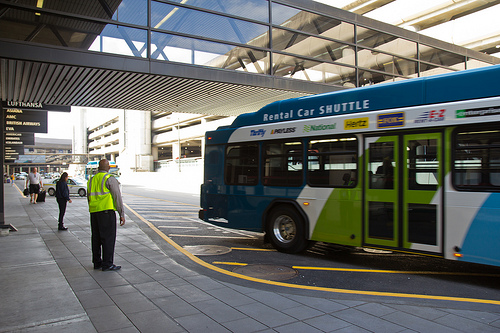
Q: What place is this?
A: It is a garage.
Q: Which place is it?
A: It is a garage.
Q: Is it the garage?
A: Yes, it is the garage.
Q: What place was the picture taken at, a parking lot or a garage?
A: It was taken at a garage.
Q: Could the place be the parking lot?
A: No, it is the garage.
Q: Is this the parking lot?
A: No, it is the garage.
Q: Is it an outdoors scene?
A: Yes, it is outdoors.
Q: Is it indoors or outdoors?
A: It is outdoors.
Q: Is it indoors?
A: No, it is outdoors.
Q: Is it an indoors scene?
A: No, it is outdoors.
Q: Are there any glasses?
A: No, there are no glasses.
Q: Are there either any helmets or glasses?
A: No, there are no glasses or helmets.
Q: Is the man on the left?
A: Yes, the man is on the left of the image.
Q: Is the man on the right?
A: No, the man is on the left of the image.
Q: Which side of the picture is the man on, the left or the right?
A: The man is on the left of the image.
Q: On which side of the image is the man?
A: The man is on the left of the image.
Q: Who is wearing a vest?
A: The man is wearing a vest.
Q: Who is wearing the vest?
A: The man is wearing a vest.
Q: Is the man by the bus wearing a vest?
A: Yes, the man is wearing a vest.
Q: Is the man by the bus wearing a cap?
A: No, the man is wearing a vest.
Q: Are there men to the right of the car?
A: Yes, there is a man to the right of the car.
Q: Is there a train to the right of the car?
A: No, there is a man to the right of the car.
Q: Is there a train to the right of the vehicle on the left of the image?
A: No, there is a man to the right of the car.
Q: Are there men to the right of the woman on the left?
A: Yes, there is a man to the right of the woman.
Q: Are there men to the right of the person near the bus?
A: Yes, there is a man to the right of the woman.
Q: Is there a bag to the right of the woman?
A: No, there is a man to the right of the woman.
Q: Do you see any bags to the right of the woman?
A: No, there is a man to the right of the woman.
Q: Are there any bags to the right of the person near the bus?
A: No, there is a man to the right of the woman.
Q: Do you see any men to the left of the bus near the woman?
A: Yes, there is a man to the left of the bus.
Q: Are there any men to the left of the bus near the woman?
A: Yes, there is a man to the left of the bus.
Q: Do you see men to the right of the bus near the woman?
A: No, the man is to the left of the bus.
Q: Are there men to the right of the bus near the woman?
A: No, the man is to the left of the bus.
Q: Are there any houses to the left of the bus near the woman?
A: No, there is a man to the left of the bus.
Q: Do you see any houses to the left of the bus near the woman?
A: No, there is a man to the left of the bus.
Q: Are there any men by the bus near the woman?
A: Yes, there is a man by the bus.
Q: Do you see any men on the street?
A: Yes, there is a man on the street.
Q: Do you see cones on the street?
A: No, there is a man on the street.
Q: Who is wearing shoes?
A: The man is wearing shoes.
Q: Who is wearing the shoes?
A: The man is wearing shoes.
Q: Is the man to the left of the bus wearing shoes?
A: Yes, the man is wearing shoes.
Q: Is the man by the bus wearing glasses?
A: No, the man is wearing shoes.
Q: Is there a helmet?
A: No, there are no helmets.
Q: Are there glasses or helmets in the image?
A: No, there are no helmets or glasses.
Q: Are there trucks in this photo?
A: No, there are no trucks.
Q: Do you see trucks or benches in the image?
A: No, there are no trucks or benches.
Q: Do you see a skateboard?
A: No, there are no skateboards.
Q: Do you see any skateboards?
A: No, there are no skateboards.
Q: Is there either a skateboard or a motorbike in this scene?
A: No, there are no skateboards or motorcycles.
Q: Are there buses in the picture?
A: Yes, there is a bus.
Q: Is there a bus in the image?
A: Yes, there is a bus.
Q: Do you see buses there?
A: Yes, there is a bus.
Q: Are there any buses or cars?
A: Yes, there is a bus.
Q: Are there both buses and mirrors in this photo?
A: No, there is a bus but no mirrors.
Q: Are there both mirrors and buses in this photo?
A: No, there is a bus but no mirrors.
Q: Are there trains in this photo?
A: No, there are no trains.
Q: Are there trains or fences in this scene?
A: No, there are no trains or fences.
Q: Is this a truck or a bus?
A: This is a bus.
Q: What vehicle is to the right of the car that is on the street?
A: The vehicle is a bus.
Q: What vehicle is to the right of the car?
A: The vehicle is a bus.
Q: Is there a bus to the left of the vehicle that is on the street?
A: No, the bus is to the right of the car.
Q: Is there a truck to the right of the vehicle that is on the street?
A: No, there is a bus to the right of the car.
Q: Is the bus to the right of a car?
A: Yes, the bus is to the right of a car.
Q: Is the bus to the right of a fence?
A: No, the bus is to the right of a car.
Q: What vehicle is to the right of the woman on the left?
A: The vehicle is a bus.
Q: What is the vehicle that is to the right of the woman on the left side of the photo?
A: The vehicle is a bus.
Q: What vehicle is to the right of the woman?
A: The vehicle is a bus.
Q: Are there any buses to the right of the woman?
A: Yes, there is a bus to the right of the woman.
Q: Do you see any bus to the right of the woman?
A: Yes, there is a bus to the right of the woman.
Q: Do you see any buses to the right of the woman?
A: Yes, there is a bus to the right of the woman.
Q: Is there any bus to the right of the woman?
A: Yes, there is a bus to the right of the woman.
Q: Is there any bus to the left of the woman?
A: No, the bus is to the right of the woman.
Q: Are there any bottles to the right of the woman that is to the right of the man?
A: No, there is a bus to the right of the woman.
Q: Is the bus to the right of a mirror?
A: No, the bus is to the right of a woman.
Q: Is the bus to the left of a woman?
A: No, the bus is to the right of a woman.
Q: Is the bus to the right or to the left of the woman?
A: The bus is to the right of the woman.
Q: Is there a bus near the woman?
A: Yes, there is a bus near the woman.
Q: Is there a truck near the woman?
A: No, there is a bus near the woman.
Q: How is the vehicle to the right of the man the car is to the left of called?
A: The vehicle is a bus.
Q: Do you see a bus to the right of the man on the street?
A: Yes, there is a bus to the right of the man.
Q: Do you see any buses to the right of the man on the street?
A: Yes, there is a bus to the right of the man.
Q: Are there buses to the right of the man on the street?
A: Yes, there is a bus to the right of the man.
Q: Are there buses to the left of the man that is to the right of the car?
A: No, the bus is to the right of the man.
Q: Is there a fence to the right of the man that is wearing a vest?
A: No, there is a bus to the right of the man.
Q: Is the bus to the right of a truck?
A: No, the bus is to the right of the man.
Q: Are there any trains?
A: No, there are no trains.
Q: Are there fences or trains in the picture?
A: No, there are no trains or fences.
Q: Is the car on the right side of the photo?
A: No, the car is on the left of the image.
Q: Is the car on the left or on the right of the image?
A: The car is on the left of the image.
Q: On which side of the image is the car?
A: The car is on the left of the image.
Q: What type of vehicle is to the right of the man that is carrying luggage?
A: The vehicle is a car.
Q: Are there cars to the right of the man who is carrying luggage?
A: Yes, there is a car to the right of the man.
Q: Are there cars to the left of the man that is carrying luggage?
A: No, the car is to the right of the man.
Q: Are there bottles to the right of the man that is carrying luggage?
A: No, there is a car to the right of the man.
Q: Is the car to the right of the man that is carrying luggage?
A: Yes, the car is to the right of the man.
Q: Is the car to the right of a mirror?
A: No, the car is to the right of the man.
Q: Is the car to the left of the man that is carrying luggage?
A: No, the car is to the right of the man.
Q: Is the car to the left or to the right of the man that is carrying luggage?
A: The car is to the right of the man.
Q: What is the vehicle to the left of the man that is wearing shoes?
A: The vehicle is a car.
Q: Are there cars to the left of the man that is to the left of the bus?
A: Yes, there is a car to the left of the man.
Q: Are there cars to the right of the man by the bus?
A: No, the car is to the left of the man.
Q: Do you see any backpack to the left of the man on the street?
A: No, there is a car to the left of the man.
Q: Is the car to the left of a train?
A: No, the car is to the left of a man.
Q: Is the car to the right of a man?
A: No, the car is to the left of a man.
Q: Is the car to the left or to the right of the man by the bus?
A: The car is to the left of the man.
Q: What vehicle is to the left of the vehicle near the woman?
A: The vehicle is a car.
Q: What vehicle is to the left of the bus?
A: The vehicle is a car.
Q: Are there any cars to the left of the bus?
A: Yes, there is a car to the left of the bus.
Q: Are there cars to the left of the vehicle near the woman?
A: Yes, there is a car to the left of the bus.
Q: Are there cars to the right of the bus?
A: No, the car is to the left of the bus.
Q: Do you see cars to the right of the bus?
A: No, the car is to the left of the bus.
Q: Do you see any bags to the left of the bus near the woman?
A: No, there is a car to the left of the bus.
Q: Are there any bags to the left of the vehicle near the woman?
A: No, there is a car to the left of the bus.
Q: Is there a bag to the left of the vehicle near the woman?
A: No, there is a car to the left of the bus.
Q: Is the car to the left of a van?
A: No, the car is to the left of the bus.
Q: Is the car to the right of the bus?
A: No, the car is to the left of the bus.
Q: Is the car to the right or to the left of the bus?
A: The car is to the left of the bus.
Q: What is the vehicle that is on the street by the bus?
A: The vehicle is a car.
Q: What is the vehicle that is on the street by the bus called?
A: The vehicle is a car.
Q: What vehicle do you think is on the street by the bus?
A: The vehicle is a car.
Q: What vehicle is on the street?
A: The vehicle is a car.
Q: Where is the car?
A: The car is on the street.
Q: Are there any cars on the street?
A: Yes, there is a car on the street.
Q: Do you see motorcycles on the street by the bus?
A: No, there is a car on the street.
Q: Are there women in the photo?
A: Yes, there is a woman.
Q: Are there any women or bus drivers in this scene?
A: Yes, there is a woman.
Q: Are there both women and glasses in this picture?
A: No, there is a woman but no glasses.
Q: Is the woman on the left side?
A: Yes, the woman is on the left of the image.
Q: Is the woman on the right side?
A: No, the woman is on the left of the image.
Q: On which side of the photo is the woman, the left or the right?
A: The woman is on the left of the image.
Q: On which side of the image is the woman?
A: The woman is on the left of the image.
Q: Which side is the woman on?
A: The woman is on the left of the image.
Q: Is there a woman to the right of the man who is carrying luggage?
A: Yes, there is a woman to the right of the man.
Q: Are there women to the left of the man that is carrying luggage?
A: No, the woman is to the right of the man.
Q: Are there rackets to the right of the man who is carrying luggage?
A: No, there is a woman to the right of the man.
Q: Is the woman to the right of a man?
A: Yes, the woman is to the right of a man.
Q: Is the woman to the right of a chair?
A: No, the woman is to the right of a man.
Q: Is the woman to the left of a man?
A: No, the woman is to the right of a man.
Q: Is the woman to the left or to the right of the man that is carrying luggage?
A: The woman is to the right of the man.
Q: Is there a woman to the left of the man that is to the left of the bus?
A: Yes, there is a woman to the left of the man.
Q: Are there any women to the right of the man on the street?
A: No, the woman is to the left of the man.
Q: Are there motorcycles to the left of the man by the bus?
A: No, there is a woman to the left of the man.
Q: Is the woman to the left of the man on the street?
A: Yes, the woman is to the left of the man.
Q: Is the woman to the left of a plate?
A: No, the woman is to the left of the man.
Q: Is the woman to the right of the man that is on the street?
A: No, the woman is to the left of the man.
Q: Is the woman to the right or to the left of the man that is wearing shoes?
A: The woman is to the left of the man.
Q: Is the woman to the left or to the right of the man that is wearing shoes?
A: The woman is to the left of the man.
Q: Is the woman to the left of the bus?
A: Yes, the woman is to the left of the bus.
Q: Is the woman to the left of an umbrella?
A: No, the woman is to the left of the bus.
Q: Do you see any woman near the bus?
A: Yes, there is a woman near the bus.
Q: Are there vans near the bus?
A: No, there is a woman near the bus.